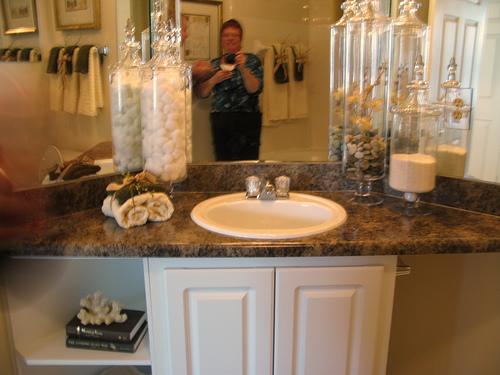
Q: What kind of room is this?
A: It is a bathroom.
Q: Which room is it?
A: It is a bathroom.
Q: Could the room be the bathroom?
A: Yes, it is the bathroom.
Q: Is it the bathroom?
A: Yes, it is the bathroom.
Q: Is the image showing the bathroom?
A: Yes, it is showing the bathroom.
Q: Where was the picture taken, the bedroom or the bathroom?
A: It was taken at the bathroom.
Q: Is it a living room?
A: No, it is a bathroom.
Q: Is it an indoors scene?
A: Yes, it is indoors.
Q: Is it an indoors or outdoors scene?
A: It is indoors.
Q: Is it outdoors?
A: No, it is indoors.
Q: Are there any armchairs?
A: No, there are no armchairs.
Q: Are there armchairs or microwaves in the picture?
A: No, there are no armchairs or microwaves.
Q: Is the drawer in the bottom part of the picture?
A: Yes, the drawer is in the bottom of the image.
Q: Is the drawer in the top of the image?
A: No, the drawer is in the bottom of the image.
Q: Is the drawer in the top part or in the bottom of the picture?
A: The drawer is in the bottom of the image.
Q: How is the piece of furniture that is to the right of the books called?
A: The piece of furniture is a drawer.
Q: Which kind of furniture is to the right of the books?
A: The piece of furniture is a drawer.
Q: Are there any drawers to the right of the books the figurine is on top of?
A: Yes, there is a drawer to the right of the books.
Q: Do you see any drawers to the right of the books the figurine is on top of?
A: Yes, there is a drawer to the right of the books.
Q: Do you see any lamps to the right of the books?
A: No, there is a drawer to the right of the books.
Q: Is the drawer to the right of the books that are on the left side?
A: Yes, the drawer is to the right of the books.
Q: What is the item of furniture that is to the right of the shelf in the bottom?
A: The piece of furniture is a drawer.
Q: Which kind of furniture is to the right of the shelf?
A: The piece of furniture is a drawer.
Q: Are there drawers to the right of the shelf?
A: Yes, there is a drawer to the right of the shelf.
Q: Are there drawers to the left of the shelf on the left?
A: No, the drawer is to the right of the shelf.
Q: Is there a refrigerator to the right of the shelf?
A: No, there is a drawer to the right of the shelf.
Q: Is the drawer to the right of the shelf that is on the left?
A: Yes, the drawer is to the right of the shelf.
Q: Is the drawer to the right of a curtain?
A: No, the drawer is to the right of the shelf.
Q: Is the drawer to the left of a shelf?
A: No, the drawer is to the right of a shelf.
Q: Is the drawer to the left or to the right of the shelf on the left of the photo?
A: The drawer is to the right of the shelf.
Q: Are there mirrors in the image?
A: Yes, there is a mirror.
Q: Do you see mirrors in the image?
A: Yes, there is a mirror.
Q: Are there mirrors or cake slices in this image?
A: Yes, there is a mirror.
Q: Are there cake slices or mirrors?
A: Yes, there is a mirror.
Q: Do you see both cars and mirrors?
A: No, there is a mirror but no cars.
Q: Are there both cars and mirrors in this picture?
A: No, there is a mirror but no cars.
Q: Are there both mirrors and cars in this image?
A: No, there is a mirror but no cars.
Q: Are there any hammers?
A: No, there are no hammers.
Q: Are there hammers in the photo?
A: No, there are no hammers.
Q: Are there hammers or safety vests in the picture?
A: No, there are no hammers or safety vests.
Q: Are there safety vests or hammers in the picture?
A: No, there are no hammers or safety vests.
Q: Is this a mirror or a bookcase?
A: This is a mirror.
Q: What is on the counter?
A: The mirror is on the counter.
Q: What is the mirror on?
A: The mirror is on the counter.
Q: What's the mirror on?
A: The mirror is on the counter.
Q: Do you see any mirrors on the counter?
A: Yes, there is a mirror on the counter.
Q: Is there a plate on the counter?
A: No, there is a mirror on the counter.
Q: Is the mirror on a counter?
A: Yes, the mirror is on a counter.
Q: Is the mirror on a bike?
A: No, the mirror is on a counter.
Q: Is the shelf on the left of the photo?
A: Yes, the shelf is on the left of the image.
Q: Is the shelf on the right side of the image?
A: No, the shelf is on the left of the image.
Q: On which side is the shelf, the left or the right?
A: The shelf is on the left of the image.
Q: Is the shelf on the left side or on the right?
A: The shelf is on the left of the image.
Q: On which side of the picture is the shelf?
A: The shelf is on the left of the image.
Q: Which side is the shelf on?
A: The shelf is on the left of the image.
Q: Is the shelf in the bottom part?
A: Yes, the shelf is in the bottom of the image.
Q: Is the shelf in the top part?
A: No, the shelf is in the bottom of the image.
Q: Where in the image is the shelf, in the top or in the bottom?
A: The shelf is in the bottom of the image.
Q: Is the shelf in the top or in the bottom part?
A: The shelf is in the bottom of the image.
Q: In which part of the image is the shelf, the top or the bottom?
A: The shelf is in the bottom of the image.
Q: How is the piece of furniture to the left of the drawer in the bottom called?
A: The piece of furniture is a shelf.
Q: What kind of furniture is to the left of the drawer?
A: The piece of furniture is a shelf.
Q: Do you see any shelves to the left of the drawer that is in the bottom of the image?
A: Yes, there is a shelf to the left of the drawer.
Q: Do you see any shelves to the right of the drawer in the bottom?
A: No, the shelf is to the left of the drawer.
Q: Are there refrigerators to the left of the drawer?
A: No, there is a shelf to the left of the drawer.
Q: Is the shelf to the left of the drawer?
A: Yes, the shelf is to the left of the drawer.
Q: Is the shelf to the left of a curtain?
A: No, the shelf is to the left of the drawer.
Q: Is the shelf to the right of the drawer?
A: No, the shelf is to the left of the drawer.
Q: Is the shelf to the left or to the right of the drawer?
A: The shelf is to the left of the drawer.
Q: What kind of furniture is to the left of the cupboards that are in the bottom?
A: The piece of furniture is a shelf.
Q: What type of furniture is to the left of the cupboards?
A: The piece of furniture is a shelf.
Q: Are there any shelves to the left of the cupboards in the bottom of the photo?
A: Yes, there is a shelf to the left of the cupboards.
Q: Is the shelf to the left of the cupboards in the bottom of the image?
A: Yes, the shelf is to the left of the cupboards.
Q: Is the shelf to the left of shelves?
A: No, the shelf is to the left of the cupboards.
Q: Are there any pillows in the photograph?
A: No, there are no pillows.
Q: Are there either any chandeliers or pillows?
A: No, there are no pillows or chandeliers.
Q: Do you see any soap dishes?
A: No, there are no soap dishes.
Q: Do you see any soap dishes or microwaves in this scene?
A: No, there are no soap dishes or microwaves.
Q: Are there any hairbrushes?
A: No, there are no hairbrushes.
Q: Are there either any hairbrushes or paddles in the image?
A: No, there are no hairbrushes or paddles.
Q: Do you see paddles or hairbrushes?
A: No, there are no hairbrushes or paddles.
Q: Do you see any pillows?
A: No, there are no pillows.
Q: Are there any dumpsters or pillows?
A: No, there are no pillows or dumpsters.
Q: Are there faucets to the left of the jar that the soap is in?
A: Yes, there is a faucet to the left of the jar.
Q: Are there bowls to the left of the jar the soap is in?
A: No, there is a faucet to the left of the jar.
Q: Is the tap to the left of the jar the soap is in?
A: Yes, the tap is to the left of the jar.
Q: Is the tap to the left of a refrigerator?
A: No, the tap is to the left of the jar.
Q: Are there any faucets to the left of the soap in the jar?
A: Yes, there is a faucet to the left of the soap.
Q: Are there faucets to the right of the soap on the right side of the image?
A: No, the faucet is to the left of the soap.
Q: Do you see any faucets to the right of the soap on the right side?
A: No, the faucet is to the left of the soap.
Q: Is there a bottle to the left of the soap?
A: No, there is a faucet to the left of the soap.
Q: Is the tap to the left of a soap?
A: Yes, the tap is to the left of a soap.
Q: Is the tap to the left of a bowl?
A: No, the tap is to the left of a soap.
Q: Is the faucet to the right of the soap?
A: No, the faucet is to the left of the soap.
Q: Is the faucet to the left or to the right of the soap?
A: The faucet is to the left of the soap.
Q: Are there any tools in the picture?
A: No, there are no tools.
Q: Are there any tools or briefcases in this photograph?
A: No, there are no tools or briefcases.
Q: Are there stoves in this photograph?
A: No, there are no stoves.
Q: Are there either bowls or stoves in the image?
A: No, there are no stoves or bowls.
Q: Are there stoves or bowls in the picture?
A: No, there are no stoves or bowls.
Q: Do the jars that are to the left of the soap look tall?
A: Yes, the jars are tall.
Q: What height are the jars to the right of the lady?
A: The jars are tall.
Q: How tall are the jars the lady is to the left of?
A: The jars are tall.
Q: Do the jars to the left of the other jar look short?
A: No, the jars are tall.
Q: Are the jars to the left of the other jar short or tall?
A: The jars are tall.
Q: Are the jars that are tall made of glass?
A: Yes, the jars are made of glass.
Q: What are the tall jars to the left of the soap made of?
A: The jars are made of glass.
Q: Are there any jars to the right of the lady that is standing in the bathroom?
A: Yes, there are jars to the right of the lady.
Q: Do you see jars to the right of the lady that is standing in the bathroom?
A: Yes, there are jars to the right of the lady.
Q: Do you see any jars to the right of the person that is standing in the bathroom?
A: Yes, there are jars to the right of the lady.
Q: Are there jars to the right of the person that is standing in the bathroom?
A: Yes, there are jars to the right of the lady.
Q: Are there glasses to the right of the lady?
A: No, there are jars to the right of the lady.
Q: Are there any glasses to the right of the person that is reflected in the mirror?
A: No, there are jars to the right of the lady.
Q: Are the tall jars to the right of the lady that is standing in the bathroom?
A: Yes, the jars are to the right of the lady.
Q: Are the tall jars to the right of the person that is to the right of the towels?
A: Yes, the jars are to the right of the lady.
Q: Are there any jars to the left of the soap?
A: Yes, there are jars to the left of the soap.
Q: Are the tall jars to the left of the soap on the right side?
A: Yes, the jars are to the left of the soap.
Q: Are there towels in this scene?
A: Yes, there is a towel.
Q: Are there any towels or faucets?
A: Yes, there is a towel.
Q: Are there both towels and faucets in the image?
A: Yes, there are both a towel and a faucet.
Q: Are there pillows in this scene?
A: No, there are no pillows.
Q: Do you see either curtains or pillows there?
A: No, there are no pillows or curtains.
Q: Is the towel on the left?
A: Yes, the towel is on the left of the image.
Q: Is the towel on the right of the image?
A: No, the towel is on the left of the image.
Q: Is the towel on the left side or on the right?
A: The towel is on the left of the image.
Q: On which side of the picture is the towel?
A: The towel is on the left of the image.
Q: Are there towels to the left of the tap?
A: Yes, there is a towel to the left of the tap.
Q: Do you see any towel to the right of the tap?
A: No, the towel is to the left of the tap.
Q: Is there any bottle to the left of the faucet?
A: No, there is a towel to the left of the faucet.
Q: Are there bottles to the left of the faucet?
A: No, there is a towel to the left of the faucet.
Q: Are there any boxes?
A: No, there are no boxes.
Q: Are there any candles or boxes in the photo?
A: No, there are no boxes or candles.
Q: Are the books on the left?
A: Yes, the books are on the left of the image.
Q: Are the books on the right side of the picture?
A: No, the books are on the left of the image.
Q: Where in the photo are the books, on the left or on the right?
A: The books are on the left of the image.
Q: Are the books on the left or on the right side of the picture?
A: The books are on the left of the image.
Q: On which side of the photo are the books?
A: The books are on the left of the image.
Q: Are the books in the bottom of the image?
A: Yes, the books are in the bottom of the image.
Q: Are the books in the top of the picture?
A: No, the books are in the bottom of the image.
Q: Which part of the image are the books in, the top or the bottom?
A: The books are in the bottom of the image.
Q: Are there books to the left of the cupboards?
A: Yes, there are books to the left of the cupboards.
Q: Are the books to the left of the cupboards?
A: Yes, the books are to the left of the cupboards.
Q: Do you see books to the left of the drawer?
A: Yes, there are books to the left of the drawer.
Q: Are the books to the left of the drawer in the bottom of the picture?
A: Yes, the books are to the left of the drawer.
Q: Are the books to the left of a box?
A: No, the books are to the left of the drawer.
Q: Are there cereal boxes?
A: No, there are no cereal boxes.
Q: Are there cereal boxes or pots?
A: No, there are no cereal boxes or pots.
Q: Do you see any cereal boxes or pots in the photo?
A: No, there are no cereal boxes or pots.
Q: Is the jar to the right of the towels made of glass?
A: Yes, the jar is made of glass.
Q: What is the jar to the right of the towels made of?
A: The jar is made of glass.